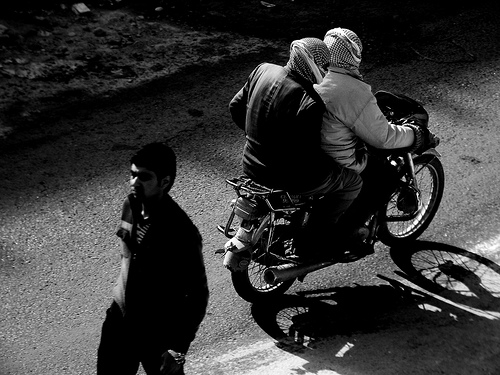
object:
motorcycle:
[214, 90, 444, 303]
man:
[97, 141, 215, 374]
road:
[0, 34, 499, 372]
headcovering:
[284, 36, 336, 86]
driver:
[315, 69, 421, 177]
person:
[230, 37, 347, 239]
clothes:
[226, 62, 366, 242]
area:
[8, 34, 230, 135]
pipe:
[264, 262, 310, 284]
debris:
[68, 2, 108, 29]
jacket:
[317, 73, 414, 174]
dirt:
[4, 3, 287, 61]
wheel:
[219, 215, 306, 304]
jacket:
[225, 61, 336, 198]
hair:
[131, 141, 180, 177]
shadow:
[241, 242, 500, 374]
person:
[313, 24, 411, 166]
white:
[330, 84, 358, 122]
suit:
[95, 201, 209, 375]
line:
[346, 241, 490, 343]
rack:
[225, 173, 267, 197]